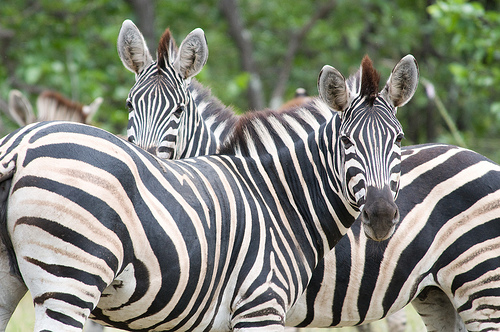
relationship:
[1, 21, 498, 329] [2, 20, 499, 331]
two striped zebras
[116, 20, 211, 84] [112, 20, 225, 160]
ears of zebra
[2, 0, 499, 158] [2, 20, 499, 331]
tree behind zebras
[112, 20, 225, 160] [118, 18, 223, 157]
zebra has stripes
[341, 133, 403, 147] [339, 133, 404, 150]
pair zebra eyes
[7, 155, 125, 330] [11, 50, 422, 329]
hind leg zebra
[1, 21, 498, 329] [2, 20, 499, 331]
four zebras seen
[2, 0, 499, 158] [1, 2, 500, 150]
trees in background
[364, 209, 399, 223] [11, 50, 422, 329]
nostrils of zebra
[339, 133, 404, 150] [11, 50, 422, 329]
eyes of zebra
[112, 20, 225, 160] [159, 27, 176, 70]
zebra ear mane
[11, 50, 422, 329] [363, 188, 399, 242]
zebra has snout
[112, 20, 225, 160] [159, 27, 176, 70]
zebra ears mane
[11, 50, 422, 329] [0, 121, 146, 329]
zebra has backside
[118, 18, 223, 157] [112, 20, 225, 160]
stripes black white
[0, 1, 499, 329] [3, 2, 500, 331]
picture taken outdoors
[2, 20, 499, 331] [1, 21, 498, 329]
zebras black white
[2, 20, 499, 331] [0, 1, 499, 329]
zebras looking camera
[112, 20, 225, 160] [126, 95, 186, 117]
zebra black eyes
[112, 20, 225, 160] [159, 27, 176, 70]
zebra's mane brown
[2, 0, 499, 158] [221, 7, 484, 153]
leaves on tree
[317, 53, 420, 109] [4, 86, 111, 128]
top of head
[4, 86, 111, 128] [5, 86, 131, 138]
head of zebra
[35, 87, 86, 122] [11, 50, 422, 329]
mane of zebra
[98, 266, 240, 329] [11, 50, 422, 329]
belly of zebra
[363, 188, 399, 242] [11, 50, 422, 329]
muzzle of zebra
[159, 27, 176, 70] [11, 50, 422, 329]
front of zebra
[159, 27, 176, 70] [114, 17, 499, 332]
front of zebra